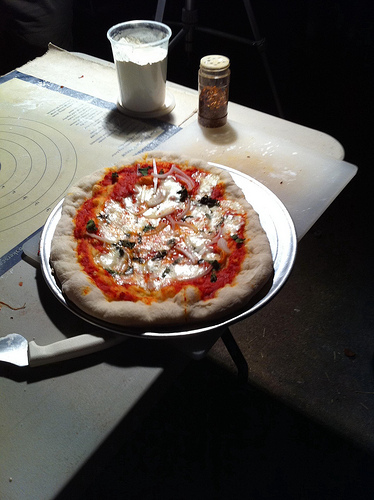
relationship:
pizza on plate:
[106, 169, 239, 310] [266, 203, 297, 238]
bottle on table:
[198, 53, 231, 128] [260, 135, 317, 194]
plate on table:
[266, 203, 297, 238] [260, 135, 317, 194]